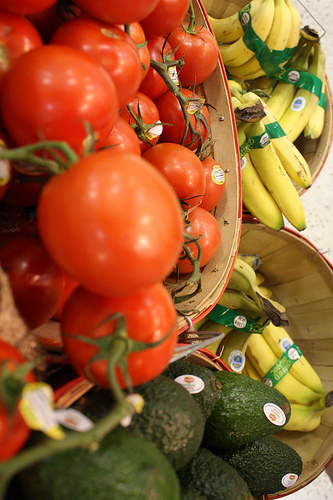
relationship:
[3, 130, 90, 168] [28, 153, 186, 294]
stem attached to tomato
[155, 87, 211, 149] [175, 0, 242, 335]
tomato in basket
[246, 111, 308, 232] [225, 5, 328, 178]
banana in basket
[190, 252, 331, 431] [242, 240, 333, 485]
bananas in basket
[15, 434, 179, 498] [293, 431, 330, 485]
avacado in basket